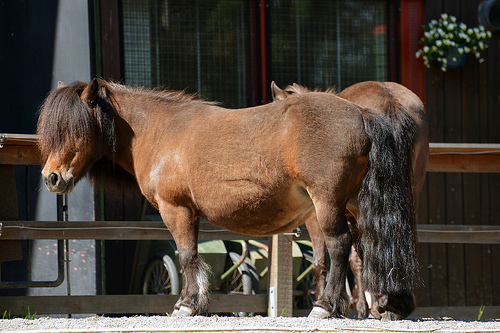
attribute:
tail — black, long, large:
[358, 112, 422, 292]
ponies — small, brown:
[36, 75, 430, 318]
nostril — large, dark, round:
[47, 172, 60, 187]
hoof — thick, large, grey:
[155, 291, 202, 321]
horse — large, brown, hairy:
[31, 72, 416, 321]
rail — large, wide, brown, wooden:
[3, 131, 483, 319]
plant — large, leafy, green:
[405, 10, 484, 73]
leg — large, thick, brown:
[279, 101, 370, 322]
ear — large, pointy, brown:
[80, 70, 107, 101]